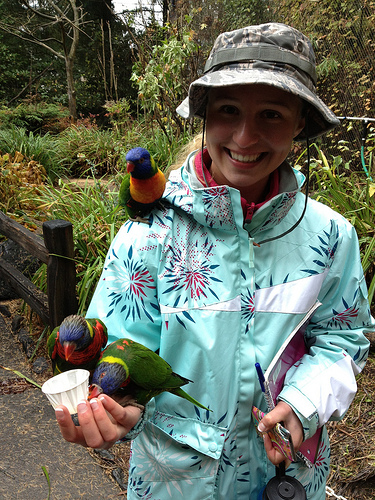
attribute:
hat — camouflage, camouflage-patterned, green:
[172, 17, 341, 144]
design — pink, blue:
[158, 237, 221, 306]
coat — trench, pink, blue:
[93, 187, 363, 492]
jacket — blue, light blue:
[83, 161, 373, 498]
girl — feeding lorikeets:
[57, 24, 373, 498]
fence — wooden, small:
[0, 208, 76, 332]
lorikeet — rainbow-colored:
[92, 349, 220, 418]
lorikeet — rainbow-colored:
[43, 309, 103, 370]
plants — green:
[22, 130, 115, 260]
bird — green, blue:
[92, 136, 178, 227]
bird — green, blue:
[39, 290, 105, 383]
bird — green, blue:
[100, 319, 206, 416]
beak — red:
[125, 161, 135, 173]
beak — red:
[61, 342, 74, 359]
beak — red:
[87, 384, 103, 400]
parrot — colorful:
[114, 146, 165, 222]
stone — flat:
[23, 442, 81, 498]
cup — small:
[44, 380, 86, 419]